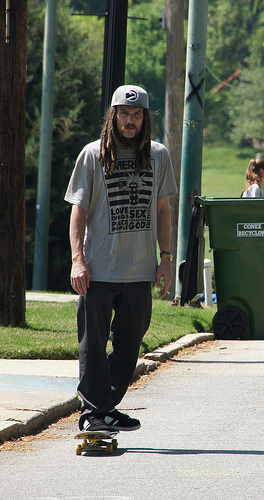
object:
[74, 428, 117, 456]
skateboard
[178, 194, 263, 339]
trash can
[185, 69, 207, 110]
black x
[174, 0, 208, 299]
pole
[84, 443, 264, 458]
shadow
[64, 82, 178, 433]
skateboarder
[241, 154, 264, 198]
woman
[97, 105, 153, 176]
dreadlocks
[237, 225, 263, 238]
recycle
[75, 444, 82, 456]
wheels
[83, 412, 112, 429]
shoes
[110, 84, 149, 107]
cap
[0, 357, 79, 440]
sidewalk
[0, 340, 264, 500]
street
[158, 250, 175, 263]
wristwatch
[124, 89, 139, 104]
logo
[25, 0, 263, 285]
tree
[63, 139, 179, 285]
shirt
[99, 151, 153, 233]
black print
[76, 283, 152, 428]
pants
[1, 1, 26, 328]
power pole